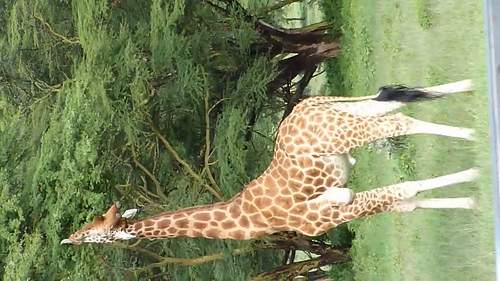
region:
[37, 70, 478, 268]
a giraffe in the wild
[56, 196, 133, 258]
the head of a giraffe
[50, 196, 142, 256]
a giraffe sticking out its tongue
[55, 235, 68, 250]
the tongue of a giraffe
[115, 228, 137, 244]
the ear of a giraffe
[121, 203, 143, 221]
the ear of a giraffe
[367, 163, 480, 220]
the front legs of a giraffe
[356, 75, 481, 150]
the back legs of a giraffe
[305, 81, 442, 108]
the tail of a giraffe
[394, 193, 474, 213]
the leg of a giraffe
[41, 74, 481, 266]
a giraffe in the wild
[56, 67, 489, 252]
a giraffe eating from a tree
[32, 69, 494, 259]
a giraffe sticking out its tongue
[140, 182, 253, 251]
the neck of a giraffe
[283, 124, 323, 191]
the spots of a giraffe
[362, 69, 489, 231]
the legs of a giraffe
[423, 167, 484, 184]
the leg of a giraffe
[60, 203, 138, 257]
head of the giraffe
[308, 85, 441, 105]
tail of the giraffe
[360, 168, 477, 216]
front legs of the giraffe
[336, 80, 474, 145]
back legs of the giraffe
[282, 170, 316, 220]
spotted pattern on giraffe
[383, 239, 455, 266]
grass on the ground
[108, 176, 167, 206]
branches on the tree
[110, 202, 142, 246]
ears of the giraffe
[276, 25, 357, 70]
trunk of the tree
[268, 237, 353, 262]
trunk of the tree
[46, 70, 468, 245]
this is a giraffe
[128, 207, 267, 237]
neck of the giraffe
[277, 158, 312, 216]
spotted pattern on the giraffe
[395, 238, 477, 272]
green grass on the ground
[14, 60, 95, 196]
leaves in the tree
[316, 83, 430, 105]
tail on the giraffe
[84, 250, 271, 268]
branch of the tree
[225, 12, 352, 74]
a large tree trunk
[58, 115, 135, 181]
lush green plants in the tree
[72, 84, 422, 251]
brown and white giraffe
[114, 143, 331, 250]
giraffe has long neck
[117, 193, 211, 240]
giraffe has brown mane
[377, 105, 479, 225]
giraffe has white legs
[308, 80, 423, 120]
black and brown tail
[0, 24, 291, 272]
green trees behind giraffe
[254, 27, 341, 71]
large brown trunk on tree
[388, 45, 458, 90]
grass is green and tall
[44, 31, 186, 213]
green and leafy tree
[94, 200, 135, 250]
giraffe has brown ossicles